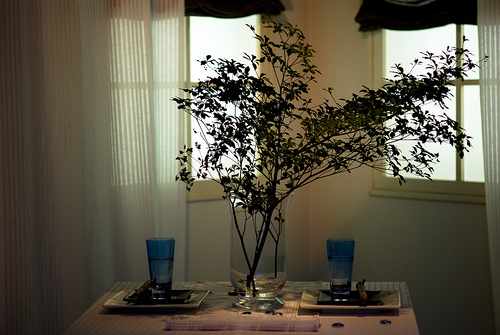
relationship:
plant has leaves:
[167, 0, 490, 298] [348, 83, 405, 112]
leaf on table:
[378, 317, 397, 327] [72, 269, 419, 333]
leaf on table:
[330, 317, 343, 330] [72, 269, 419, 333]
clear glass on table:
[326, 238, 356, 302] [107, 251, 327, 332]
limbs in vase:
[148, 20, 452, 218] [208, 163, 308, 308]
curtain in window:
[1, 0, 188, 332] [184, 12, 262, 182]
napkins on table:
[180, 300, 347, 332] [78, 253, 433, 333]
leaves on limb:
[322, 94, 373, 126] [315, 158, 336, 179]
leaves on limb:
[322, 94, 373, 126] [344, 128, 364, 150]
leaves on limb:
[322, 94, 373, 126] [357, 156, 391, 176]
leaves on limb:
[322, 94, 373, 126] [387, 134, 410, 146]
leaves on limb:
[322, 94, 373, 126] [262, 157, 280, 188]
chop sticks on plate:
[353, 275, 371, 307] [296, 282, 401, 316]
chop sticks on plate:
[125, 272, 156, 304] [296, 282, 401, 316]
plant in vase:
[158, 17, 488, 304] [313, 232, 363, 314]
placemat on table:
[163, 310, 323, 332] [63, 277, 421, 334]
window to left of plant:
[108, 24, 311, 166] [184, 17, 465, 287]